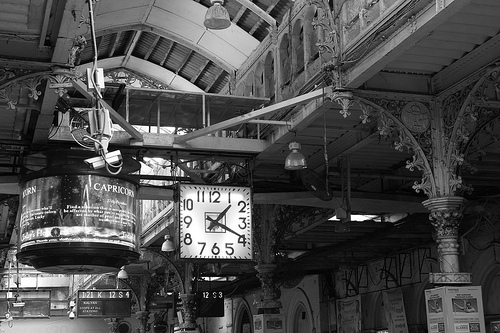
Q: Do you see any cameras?
A: Yes, there is a camera.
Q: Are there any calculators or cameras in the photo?
A: Yes, there is a camera.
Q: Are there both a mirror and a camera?
A: No, there is a camera but no mirrors.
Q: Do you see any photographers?
A: No, there are no photographers.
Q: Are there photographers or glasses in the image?
A: No, there are no photographers or glasses.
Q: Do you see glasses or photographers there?
A: No, there are no photographers or glasses.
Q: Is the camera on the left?
A: Yes, the camera is on the left of the image.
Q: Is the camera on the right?
A: No, the camera is on the left of the image.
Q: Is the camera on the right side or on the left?
A: The camera is on the left of the image.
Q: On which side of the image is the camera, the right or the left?
A: The camera is on the left of the image.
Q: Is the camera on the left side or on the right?
A: The camera is on the left of the image.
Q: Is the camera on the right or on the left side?
A: The camera is on the left of the image.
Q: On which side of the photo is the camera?
A: The camera is on the left of the image.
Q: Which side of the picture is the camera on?
A: The camera is on the left of the image.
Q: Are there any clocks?
A: Yes, there is a clock.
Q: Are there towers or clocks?
A: Yes, there is a clock.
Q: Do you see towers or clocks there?
A: Yes, there is a clock.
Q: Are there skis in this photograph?
A: No, there are no skis.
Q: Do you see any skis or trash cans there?
A: No, there are no skis or trash cans.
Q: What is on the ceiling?
A: The clock is on the ceiling.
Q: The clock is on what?
A: The clock is on the ceiling.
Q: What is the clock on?
A: The clock is on the ceiling.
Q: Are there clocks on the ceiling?
A: Yes, there is a clock on the ceiling.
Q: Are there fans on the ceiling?
A: No, there is a clock on the ceiling.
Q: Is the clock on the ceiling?
A: Yes, the clock is on the ceiling.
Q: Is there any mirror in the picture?
A: No, there are no mirrors.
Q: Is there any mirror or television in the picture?
A: No, there are no mirrors or televisions.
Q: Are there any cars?
A: No, there are no cars.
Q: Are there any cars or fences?
A: No, there are no cars or fences.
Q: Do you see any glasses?
A: No, there are no glasses.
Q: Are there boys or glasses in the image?
A: No, there are no glasses or boys.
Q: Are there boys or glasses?
A: No, there are no glasses or boys.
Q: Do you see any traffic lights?
A: No, there are no traffic lights.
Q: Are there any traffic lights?
A: No, there are no traffic lights.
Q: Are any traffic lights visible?
A: No, there are no traffic lights.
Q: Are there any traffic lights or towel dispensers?
A: No, there are no traffic lights or towel dispensers.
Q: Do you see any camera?
A: Yes, there is a camera.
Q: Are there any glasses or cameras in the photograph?
A: Yes, there is a camera.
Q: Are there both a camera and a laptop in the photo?
A: No, there is a camera but no laptops.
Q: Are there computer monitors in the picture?
A: No, there are no computer monitors.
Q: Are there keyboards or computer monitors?
A: No, there are no computer monitors or keyboards.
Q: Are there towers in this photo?
A: No, there are no towers.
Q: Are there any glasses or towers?
A: No, there are no towers or glasses.